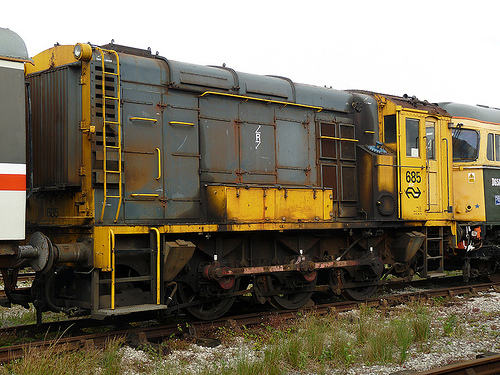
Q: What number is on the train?
A: 685.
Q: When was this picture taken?
A: Daytime.